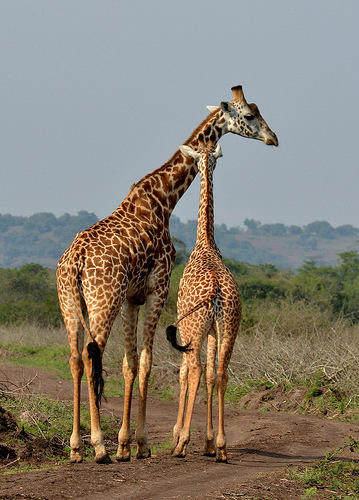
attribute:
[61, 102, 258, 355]
giraffe — adult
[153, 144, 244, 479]
giraffe — standing, shorter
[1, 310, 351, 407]
grass — long, brown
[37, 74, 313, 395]
giraffe — adult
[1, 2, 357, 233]
sky — blue, gray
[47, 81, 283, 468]
giraffe — taller, adult, standing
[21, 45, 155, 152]
clouds — white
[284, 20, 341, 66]
sky — blue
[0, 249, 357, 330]
bush — greenest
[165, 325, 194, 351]
hair — black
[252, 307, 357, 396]
grass — tall, dry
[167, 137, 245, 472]
giraffe — small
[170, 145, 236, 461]
giraffe — standing, small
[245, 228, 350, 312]
foliage — green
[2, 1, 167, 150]
sky — blue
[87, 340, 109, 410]
hair — black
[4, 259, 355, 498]
wasteland — green